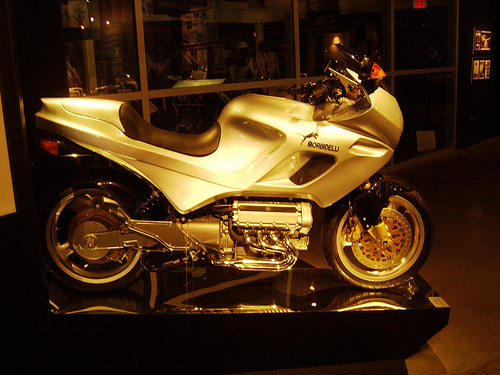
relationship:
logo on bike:
[307, 141, 339, 152] [32, 34, 436, 295]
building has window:
[1, 2, 499, 372] [139, 1, 296, 90]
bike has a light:
[32, 34, 436, 295] [43, 141, 61, 158]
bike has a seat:
[32, 34, 436, 295] [120, 102, 220, 156]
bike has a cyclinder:
[32, 34, 436, 295] [238, 225, 254, 232]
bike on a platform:
[32, 34, 436, 295] [43, 261, 449, 363]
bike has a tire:
[32, 34, 436, 295] [320, 175, 437, 289]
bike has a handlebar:
[32, 34, 436, 295] [306, 79, 344, 105]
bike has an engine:
[32, 34, 436, 295] [230, 202, 312, 236]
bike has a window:
[32, 34, 436, 295] [333, 42, 378, 90]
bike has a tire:
[32, 44, 434, 287] [320, 175, 437, 289]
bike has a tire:
[32, 34, 436, 295] [320, 190, 434, 290]